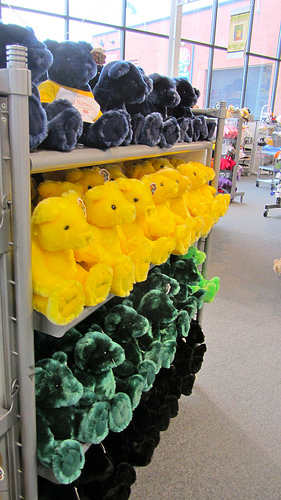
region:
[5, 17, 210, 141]
A row of navy blue stuffed bears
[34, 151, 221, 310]
A shelf of yellow stuffed teddy bears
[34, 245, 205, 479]
A shelf of dark green stuffed teddy bears with one lime green one on the end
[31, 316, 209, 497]
The bottom shelf is full of black teddy bears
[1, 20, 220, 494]
4 shelves of stuffed teddy bears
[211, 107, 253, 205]
A rack of small toys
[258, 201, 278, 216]
Wheel of a sales rack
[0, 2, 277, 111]
12 large glass windows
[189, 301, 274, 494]
Light grey colored carpet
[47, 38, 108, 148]
A navy teddy bear with a white and yellow t shirt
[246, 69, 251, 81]
a window pane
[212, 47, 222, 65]
section of a glass window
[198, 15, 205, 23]
part of a transparent window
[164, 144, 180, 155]
edge of a shelf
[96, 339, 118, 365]
face of a doll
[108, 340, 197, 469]
group of black dolls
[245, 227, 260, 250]
floor of a shop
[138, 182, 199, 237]
group of yellow dolls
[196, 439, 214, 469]
grey surface of a shop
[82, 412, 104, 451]
feet of a black doll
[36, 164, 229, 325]
two rows of stuffed yellow teddy bears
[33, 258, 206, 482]
row of dark green teddy bears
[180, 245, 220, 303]
one light green teddy bear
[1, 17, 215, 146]
row of dark blue teddy bears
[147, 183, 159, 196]
tag on stuffed teddy bear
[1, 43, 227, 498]
grey metal shelves holding stuffed teddy bears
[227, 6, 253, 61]
white banner sign hanging from window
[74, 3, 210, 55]
storefront window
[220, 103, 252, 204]
shelves of hanging children's clothes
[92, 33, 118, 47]
black lights on side of building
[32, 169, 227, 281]
bright yellow teddy bears sitting on shelf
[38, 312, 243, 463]
dark green teddy bears sitting on shelf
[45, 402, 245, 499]
black teddy bears sitting on bottom shelf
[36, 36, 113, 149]
black teddy bear wearing yellow shirt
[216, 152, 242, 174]
hot pink shirts on display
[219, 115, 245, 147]
light pink shirts on display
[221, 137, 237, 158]
white shirts on display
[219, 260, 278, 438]
beige carpet with specks of color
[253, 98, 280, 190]
display rack sitting across room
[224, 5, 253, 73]
advertising banner hung from ceiling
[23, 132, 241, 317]
A shelf of yellow teddy bears.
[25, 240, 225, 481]
A shelf of green teddy bears.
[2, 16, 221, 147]
A shelf of gray teddy bears.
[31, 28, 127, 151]
The teddy bear is wearing a yellow and white shirt.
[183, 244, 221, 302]
This teddy bear is bright green.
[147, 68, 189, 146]
A gray teddy bear.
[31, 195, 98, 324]
A yellow teddy bear.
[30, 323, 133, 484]
Two green teddy bears.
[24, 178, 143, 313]
Two yellow teddy bears.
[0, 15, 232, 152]
Teddy bears on the top shelf.